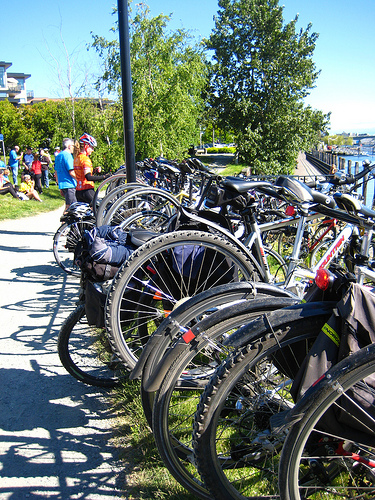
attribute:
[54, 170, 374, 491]
bikes — parked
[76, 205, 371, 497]
grass — green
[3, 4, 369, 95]
sky — blue, white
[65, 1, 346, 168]
trees — back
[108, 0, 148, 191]
pole — black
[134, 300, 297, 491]
tire — black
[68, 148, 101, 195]
shirt — orange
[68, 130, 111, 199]
person — standing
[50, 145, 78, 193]
shirt — blue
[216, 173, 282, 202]
seat — black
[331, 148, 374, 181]
water — blue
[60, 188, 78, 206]
shorts — black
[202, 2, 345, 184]
tree — green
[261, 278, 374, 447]
bikebag — black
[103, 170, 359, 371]
bike — silver, red, white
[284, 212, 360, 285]
frame — red